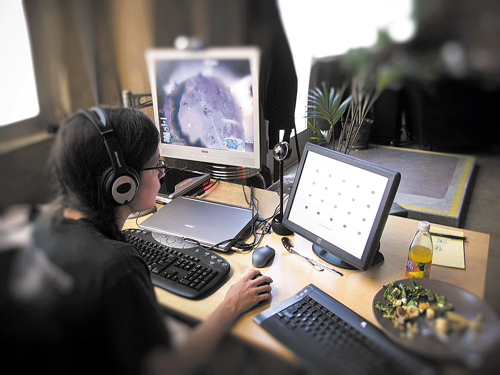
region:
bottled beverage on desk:
[403, 215, 439, 289]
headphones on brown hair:
[67, 97, 142, 211]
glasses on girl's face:
[129, 153, 172, 178]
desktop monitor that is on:
[143, 50, 264, 175]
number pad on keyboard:
[176, 260, 217, 290]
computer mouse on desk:
[249, 238, 274, 269]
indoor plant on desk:
[303, 72, 375, 157]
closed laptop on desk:
[140, 182, 255, 260]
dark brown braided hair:
[71, 195, 131, 256]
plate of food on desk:
[372, 269, 483, 371]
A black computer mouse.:
[246, 243, 276, 265]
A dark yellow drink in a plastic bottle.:
[405, 222, 434, 279]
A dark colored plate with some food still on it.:
[371, 274, 498, 361]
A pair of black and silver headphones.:
[76, 101, 139, 204]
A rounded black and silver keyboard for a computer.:
[120, 227, 231, 301]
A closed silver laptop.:
[140, 191, 260, 248]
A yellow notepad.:
[419, 225, 467, 270]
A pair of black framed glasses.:
[136, 161, 171, 173]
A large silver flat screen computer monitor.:
[141, 48, 263, 170]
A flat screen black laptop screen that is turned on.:
[281, 140, 403, 273]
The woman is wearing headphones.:
[1, 96, 175, 373]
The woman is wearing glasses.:
[47, 93, 169, 213]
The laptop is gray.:
[136, 189, 263, 258]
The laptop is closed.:
[138, 186, 261, 253]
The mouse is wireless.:
[246, 237, 280, 271]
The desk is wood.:
[116, 155, 495, 372]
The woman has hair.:
[48, 93, 165, 294]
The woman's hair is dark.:
[46, 98, 172, 251]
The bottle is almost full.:
[403, 211, 438, 291]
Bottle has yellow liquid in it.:
[402, 216, 437, 285]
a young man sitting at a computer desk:
[5, 103, 215, 370]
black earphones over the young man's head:
[70, 104, 140, 207]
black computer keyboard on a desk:
[120, 227, 235, 301]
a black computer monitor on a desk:
[280, 140, 400, 270]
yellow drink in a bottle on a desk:
[405, 219, 440, 280]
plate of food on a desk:
[370, 276, 488, 361]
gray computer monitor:
[140, 48, 260, 170]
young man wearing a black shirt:
[14, 105, 190, 372]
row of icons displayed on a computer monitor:
[298, 158, 377, 243]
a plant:
[305, 75, 355, 141]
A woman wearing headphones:
[1, 105, 271, 370]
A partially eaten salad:
[372, 278, 498, 360]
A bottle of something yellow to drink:
[405, 220, 434, 282]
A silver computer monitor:
[143, 46, 263, 172]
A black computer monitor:
[280, 141, 400, 273]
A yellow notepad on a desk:
[427, 226, 465, 268]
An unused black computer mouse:
[250, 244, 275, 268]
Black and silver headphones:
[77, 106, 140, 207]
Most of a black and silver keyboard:
[119, 226, 229, 299]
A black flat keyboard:
[250, 284, 435, 374]